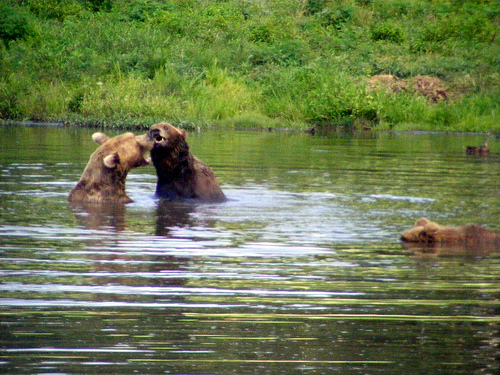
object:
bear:
[400, 218, 500, 241]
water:
[4, 118, 496, 370]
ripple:
[127, 284, 362, 301]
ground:
[15, 76, 490, 121]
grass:
[44, 62, 343, 110]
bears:
[66, 132, 155, 205]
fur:
[177, 163, 214, 186]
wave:
[234, 184, 305, 233]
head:
[92, 131, 154, 171]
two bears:
[68, 115, 228, 202]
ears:
[103, 155, 118, 168]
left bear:
[68, 131, 155, 207]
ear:
[180, 129, 188, 139]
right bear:
[149, 121, 227, 204]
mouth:
[139, 144, 153, 163]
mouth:
[152, 131, 165, 142]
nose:
[150, 128, 160, 132]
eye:
[164, 126, 168, 130]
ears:
[415, 217, 428, 225]